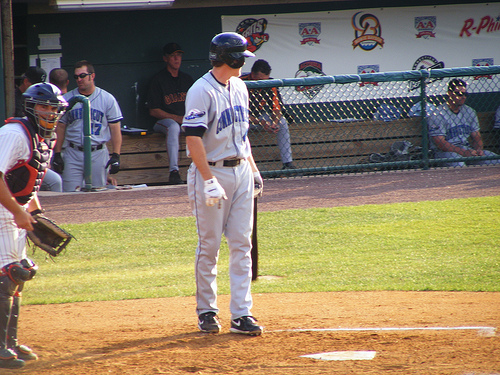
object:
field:
[17, 194, 499, 309]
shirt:
[140, 66, 213, 129]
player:
[238, 60, 295, 170]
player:
[140, 40, 196, 185]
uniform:
[423, 103, 499, 168]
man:
[13, 65, 65, 193]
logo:
[350, 11, 387, 53]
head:
[33, 101, 61, 129]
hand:
[13, 209, 40, 233]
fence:
[246, 72, 499, 175]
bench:
[110, 110, 499, 187]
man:
[49, 59, 124, 192]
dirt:
[3, 292, 500, 375]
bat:
[250, 195, 260, 281]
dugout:
[63, 4, 499, 191]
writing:
[214, 105, 254, 135]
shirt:
[180, 72, 252, 164]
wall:
[10, 0, 500, 136]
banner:
[221, 4, 499, 108]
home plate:
[13, 0, 497, 185]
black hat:
[159, 40, 183, 56]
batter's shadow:
[51, 329, 261, 366]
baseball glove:
[203, 176, 229, 211]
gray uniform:
[60, 86, 124, 192]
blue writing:
[213, 101, 259, 134]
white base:
[220, 1, 499, 108]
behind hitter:
[0, 82, 76, 362]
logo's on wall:
[294, 59, 329, 100]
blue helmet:
[21, 80, 66, 105]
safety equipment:
[24, 84, 73, 135]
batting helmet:
[21, 81, 68, 141]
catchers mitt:
[20, 209, 78, 257]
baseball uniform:
[178, 72, 299, 319]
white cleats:
[232, 318, 244, 330]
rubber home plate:
[9, 13, 243, 179]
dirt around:
[36, 165, 499, 225]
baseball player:
[181, 32, 270, 338]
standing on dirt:
[230, 304, 271, 335]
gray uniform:
[427, 101, 499, 168]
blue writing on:
[63, 102, 105, 137]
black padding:
[0, 259, 40, 285]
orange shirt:
[240, 74, 287, 116]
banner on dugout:
[409, 55, 446, 90]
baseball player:
[423, 77, 500, 167]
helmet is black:
[208, 32, 256, 64]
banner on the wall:
[456, 13, 499, 38]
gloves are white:
[203, 176, 228, 211]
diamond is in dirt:
[300, 349, 378, 362]